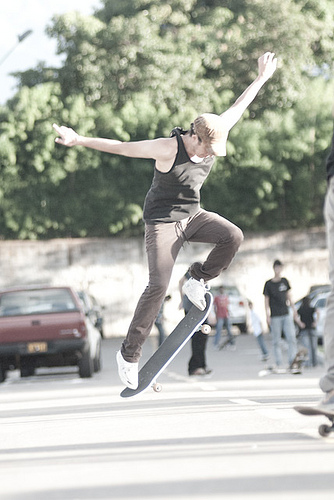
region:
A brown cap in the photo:
[199, 111, 230, 155]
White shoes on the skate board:
[116, 349, 141, 387]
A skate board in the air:
[141, 317, 205, 388]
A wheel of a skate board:
[152, 382, 165, 397]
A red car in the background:
[0, 281, 88, 350]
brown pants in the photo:
[127, 225, 177, 364]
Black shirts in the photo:
[260, 277, 291, 314]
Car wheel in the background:
[76, 347, 97, 377]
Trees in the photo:
[104, 37, 203, 105]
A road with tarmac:
[154, 399, 267, 458]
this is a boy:
[50, 61, 287, 325]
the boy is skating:
[77, 64, 283, 398]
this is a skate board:
[155, 319, 196, 383]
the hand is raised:
[221, 47, 284, 124]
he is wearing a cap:
[198, 111, 227, 151]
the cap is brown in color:
[197, 114, 224, 136]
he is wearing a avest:
[167, 165, 204, 210]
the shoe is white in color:
[123, 363, 136, 382]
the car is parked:
[0, 283, 89, 362]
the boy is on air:
[77, 101, 272, 393]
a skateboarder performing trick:
[51, 49, 278, 399]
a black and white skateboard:
[120, 289, 213, 399]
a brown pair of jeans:
[118, 209, 244, 363]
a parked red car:
[0, 282, 101, 383]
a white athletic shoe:
[116, 347, 139, 390]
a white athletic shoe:
[180, 273, 208, 309]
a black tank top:
[134, 124, 218, 224]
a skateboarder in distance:
[264, 258, 305, 373]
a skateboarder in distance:
[209, 283, 238, 351]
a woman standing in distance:
[290, 297, 320, 368]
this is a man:
[81, 69, 281, 363]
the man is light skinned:
[139, 145, 170, 166]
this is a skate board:
[163, 316, 196, 349]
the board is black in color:
[162, 337, 176, 352]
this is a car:
[19, 285, 61, 333]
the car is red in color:
[15, 306, 62, 343]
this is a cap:
[207, 117, 225, 151]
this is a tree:
[95, 33, 177, 112]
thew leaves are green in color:
[85, 53, 151, 99]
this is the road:
[190, 406, 265, 476]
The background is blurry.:
[20, 26, 216, 112]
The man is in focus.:
[52, 88, 253, 321]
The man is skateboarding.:
[118, 259, 252, 411]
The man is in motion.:
[41, 90, 313, 354]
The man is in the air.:
[34, 65, 297, 297]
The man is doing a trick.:
[50, 79, 270, 314]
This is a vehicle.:
[9, 281, 114, 385]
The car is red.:
[0, 279, 92, 378]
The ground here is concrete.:
[30, 402, 310, 477]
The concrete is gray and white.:
[14, 393, 259, 493]